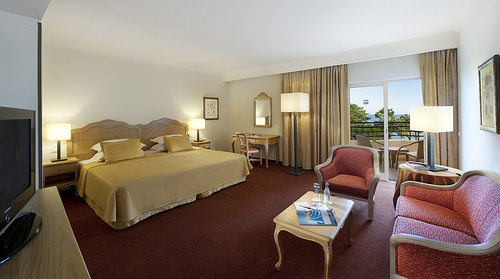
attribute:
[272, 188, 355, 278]
coffee table — tan, wood, wooden, white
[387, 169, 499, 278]
couch — pink, small, gray, red, white, grey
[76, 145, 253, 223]
bed spread — mustard yellow, tan, creme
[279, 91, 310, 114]
lamp shade — square, white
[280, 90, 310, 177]
floor lamp — tall, large, black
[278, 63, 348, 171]
curtains — floral, gold, beige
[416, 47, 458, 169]
curtains — floral, gold, beige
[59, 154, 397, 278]
carpet — burgundy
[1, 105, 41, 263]
television — flat screen, black, flatscreen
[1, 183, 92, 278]
table — wood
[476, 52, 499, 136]
art — framed, floral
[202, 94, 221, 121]
art — framed, floral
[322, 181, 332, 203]
bottle — plastic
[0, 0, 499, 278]
bedroom — well-lit, clean, nice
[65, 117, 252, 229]
bed — large, made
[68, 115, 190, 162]
headboard — wood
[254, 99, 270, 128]
mirror — hanging, framed, ornate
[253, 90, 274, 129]
frame — wood, wooden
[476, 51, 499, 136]
frame — wood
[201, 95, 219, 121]
frame — wood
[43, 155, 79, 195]
nightstand — wooden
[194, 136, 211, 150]
nightstand — wooden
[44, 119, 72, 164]
lamp — lit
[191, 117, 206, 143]
lamp — lit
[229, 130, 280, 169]
desk — wooden, wood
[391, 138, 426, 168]
chair — wicker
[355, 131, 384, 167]
chair — wicker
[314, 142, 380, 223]
armchair — red, padded, white, grey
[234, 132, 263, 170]
desk chair — wood